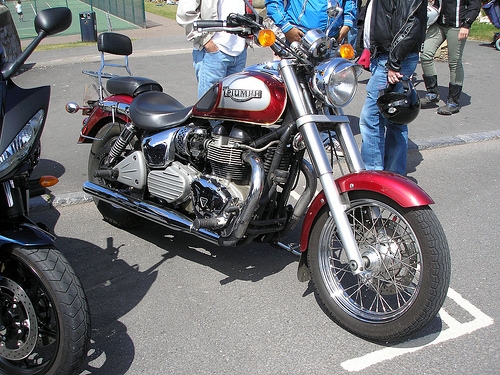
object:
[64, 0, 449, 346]
motorcycle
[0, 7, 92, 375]
motorcycle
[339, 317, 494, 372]
lines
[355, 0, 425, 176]
man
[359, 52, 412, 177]
jeans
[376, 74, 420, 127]
helmet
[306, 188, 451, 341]
front wheel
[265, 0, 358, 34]
jacket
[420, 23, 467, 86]
pants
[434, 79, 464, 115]
boots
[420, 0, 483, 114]
person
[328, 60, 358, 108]
headlight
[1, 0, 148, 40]
fence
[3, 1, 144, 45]
tennis court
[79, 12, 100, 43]
trash can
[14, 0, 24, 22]
person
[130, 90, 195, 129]
seat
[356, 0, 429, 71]
jacket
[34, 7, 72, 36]
mirror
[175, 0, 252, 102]
man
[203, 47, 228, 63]
pockets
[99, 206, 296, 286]
shadow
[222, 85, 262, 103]
logo